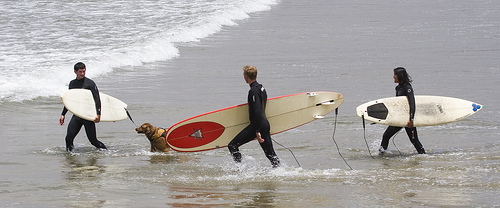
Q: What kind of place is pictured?
A: It is an ocean.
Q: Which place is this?
A: It is an ocean.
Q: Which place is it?
A: It is an ocean.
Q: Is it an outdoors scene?
A: Yes, it is outdoors.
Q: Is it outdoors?
A: Yes, it is outdoors.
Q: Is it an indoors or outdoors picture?
A: It is outdoors.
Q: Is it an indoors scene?
A: No, it is outdoors.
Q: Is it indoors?
A: No, it is outdoors.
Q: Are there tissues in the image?
A: No, there are no tissues.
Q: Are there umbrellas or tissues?
A: No, there are no tissues or umbrellas.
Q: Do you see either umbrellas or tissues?
A: No, there are no tissues or umbrellas.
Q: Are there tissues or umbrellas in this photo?
A: No, there are no tissues or umbrellas.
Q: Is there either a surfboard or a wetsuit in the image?
A: Yes, there is a wetsuit.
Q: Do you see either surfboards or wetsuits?
A: Yes, there is a wetsuit.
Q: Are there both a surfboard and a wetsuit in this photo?
A: Yes, there are both a wetsuit and a surfboard.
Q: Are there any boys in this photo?
A: No, there are no boys.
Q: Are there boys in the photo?
A: No, there are no boys.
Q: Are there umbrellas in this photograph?
A: No, there are no umbrellas.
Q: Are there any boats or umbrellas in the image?
A: No, there are no umbrellas or boats.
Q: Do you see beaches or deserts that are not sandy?
A: No, there is a beach but it is sandy.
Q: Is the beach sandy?
A: Yes, the beach is sandy.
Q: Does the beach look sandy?
A: Yes, the beach is sandy.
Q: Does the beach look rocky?
A: No, the beach is sandy.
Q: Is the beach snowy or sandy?
A: The beach is sandy.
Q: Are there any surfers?
A: Yes, there is a surfer.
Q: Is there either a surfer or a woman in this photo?
A: Yes, there is a surfer.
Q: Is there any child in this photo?
A: No, there are no children.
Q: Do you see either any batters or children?
A: No, there are no children or batters.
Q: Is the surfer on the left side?
A: Yes, the surfer is on the left of the image.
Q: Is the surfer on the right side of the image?
A: No, the surfer is on the left of the image.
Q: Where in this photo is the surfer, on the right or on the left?
A: The surfer is on the left of the image.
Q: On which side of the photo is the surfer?
A: The surfer is on the left of the image.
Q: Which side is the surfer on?
A: The surfer is on the left of the image.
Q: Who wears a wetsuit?
A: The surfer wears a wetsuit.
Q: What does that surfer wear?
A: The surfer wears a wetsuit.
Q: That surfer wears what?
A: The surfer wears a wetsuit.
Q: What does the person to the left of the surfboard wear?
A: The surfer wears a wetsuit.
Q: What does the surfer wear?
A: The surfer wears a wetsuit.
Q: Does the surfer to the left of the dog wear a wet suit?
A: Yes, the surfer wears a wet suit.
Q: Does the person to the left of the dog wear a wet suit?
A: Yes, the surfer wears a wet suit.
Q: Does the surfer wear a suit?
A: No, the surfer wears a wet suit.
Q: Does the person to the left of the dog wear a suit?
A: No, the surfer wears a wet suit.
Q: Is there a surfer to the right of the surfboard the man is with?
A: No, the surfer is to the left of the surfboard.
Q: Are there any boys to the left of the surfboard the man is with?
A: No, there is a surfer to the left of the surfboard.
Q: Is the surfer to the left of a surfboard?
A: Yes, the surfer is to the left of a surfboard.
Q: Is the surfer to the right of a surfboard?
A: No, the surfer is to the left of a surfboard.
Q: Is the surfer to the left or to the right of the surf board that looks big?
A: The surfer is to the left of the surfboard.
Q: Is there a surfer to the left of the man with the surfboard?
A: Yes, there is a surfer to the left of the man.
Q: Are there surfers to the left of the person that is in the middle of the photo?
A: Yes, there is a surfer to the left of the man.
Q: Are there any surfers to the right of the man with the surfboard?
A: No, the surfer is to the left of the man.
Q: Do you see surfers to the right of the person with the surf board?
A: No, the surfer is to the left of the man.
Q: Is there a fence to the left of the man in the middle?
A: No, there is a surfer to the left of the man.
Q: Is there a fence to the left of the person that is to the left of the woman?
A: No, there is a surfer to the left of the man.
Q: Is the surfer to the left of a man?
A: Yes, the surfer is to the left of a man.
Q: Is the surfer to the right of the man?
A: No, the surfer is to the left of the man.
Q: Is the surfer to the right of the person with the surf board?
A: No, the surfer is to the left of the man.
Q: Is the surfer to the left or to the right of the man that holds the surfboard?
A: The surfer is to the left of the man.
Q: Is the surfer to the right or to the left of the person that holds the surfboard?
A: The surfer is to the left of the man.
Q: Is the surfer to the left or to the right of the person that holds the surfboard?
A: The surfer is to the left of the man.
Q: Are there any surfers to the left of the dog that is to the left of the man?
A: Yes, there is a surfer to the left of the dog.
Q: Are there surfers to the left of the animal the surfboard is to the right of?
A: Yes, there is a surfer to the left of the dog.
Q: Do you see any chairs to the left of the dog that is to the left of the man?
A: No, there is a surfer to the left of the dog.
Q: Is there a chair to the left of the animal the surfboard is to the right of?
A: No, there is a surfer to the left of the dog.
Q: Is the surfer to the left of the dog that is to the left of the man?
A: Yes, the surfer is to the left of the dog.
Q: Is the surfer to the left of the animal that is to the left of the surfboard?
A: Yes, the surfer is to the left of the dog.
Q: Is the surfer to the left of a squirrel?
A: No, the surfer is to the left of the dog.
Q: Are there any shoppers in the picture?
A: No, there are no shoppers.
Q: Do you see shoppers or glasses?
A: No, there are no shoppers or glasses.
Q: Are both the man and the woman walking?
A: Yes, both the man and the woman are walking.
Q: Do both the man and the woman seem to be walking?
A: Yes, both the man and the woman are walking.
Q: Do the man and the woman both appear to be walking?
A: Yes, both the man and the woman are walking.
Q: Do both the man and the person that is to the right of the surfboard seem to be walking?
A: Yes, both the man and the woman are walking.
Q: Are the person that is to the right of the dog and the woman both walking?
A: Yes, both the man and the woman are walking.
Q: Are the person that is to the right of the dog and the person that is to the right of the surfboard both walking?
A: Yes, both the man and the woman are walking.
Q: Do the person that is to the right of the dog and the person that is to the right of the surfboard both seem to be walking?
A: Yes, both the man and the woman are walking.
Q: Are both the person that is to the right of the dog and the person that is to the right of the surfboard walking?
A: Yes, both the man and the woman are walking.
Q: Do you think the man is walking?
A: Yes, the man is walking.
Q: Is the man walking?
A: Yes, the man is walking.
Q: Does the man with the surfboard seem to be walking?
A: Yes, the man is walking.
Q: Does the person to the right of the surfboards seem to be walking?
A: Yes, the man is walking.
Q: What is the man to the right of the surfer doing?
A: The man is walking.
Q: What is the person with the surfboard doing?
A: The man is walking.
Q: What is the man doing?
A: The man is walking.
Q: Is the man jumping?
A: No, the man is walking.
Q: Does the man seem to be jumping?
A: No, the man is walking.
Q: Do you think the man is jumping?
A: No, the man is walking.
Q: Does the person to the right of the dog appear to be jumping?
A: No, the man is walking.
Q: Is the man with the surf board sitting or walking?
A: The man is walking.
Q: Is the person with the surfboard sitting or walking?
A: The man is walking.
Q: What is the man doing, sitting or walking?
A: The man is walking.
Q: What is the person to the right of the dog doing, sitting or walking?
A: The man is walking.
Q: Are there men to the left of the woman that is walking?
A: Yes, there is a man to the left of the woman.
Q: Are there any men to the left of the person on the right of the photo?
A: Yes, there is a man to the left of the woman.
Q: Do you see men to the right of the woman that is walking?
A: No, the man is to the left of the woman.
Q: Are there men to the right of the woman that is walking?
A: No, the man is to the left of the woman.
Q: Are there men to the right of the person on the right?
A: No, the man is to the left of the woman.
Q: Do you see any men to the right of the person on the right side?
A: No, the man is to the left of the woman.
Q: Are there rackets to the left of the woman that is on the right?
A: No, there is a man to the left of the woman.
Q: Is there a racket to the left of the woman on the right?
A: No, there is a man to the left of the woman.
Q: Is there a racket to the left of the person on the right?
A: No, there is a man to the left of the woman.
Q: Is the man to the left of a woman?
A: Yes, the man is to the left of a woman.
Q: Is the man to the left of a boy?
A: No, the man is to the left of a woman.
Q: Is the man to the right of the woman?
A: No, the man is to the left of the woman.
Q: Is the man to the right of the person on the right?
A: No, the man is to the left of the woman.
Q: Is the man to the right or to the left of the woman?
A: The man is to the left of the woman.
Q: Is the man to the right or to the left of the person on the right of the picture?
A: The man is to the left of the woman.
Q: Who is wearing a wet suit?
A: The man is wearing a wet suit.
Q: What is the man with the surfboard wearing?
A: The man is wearing a wet suit.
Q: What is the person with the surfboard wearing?
A: The man is wearing a wet suit.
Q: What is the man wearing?
A: The man is wearing a wet suit.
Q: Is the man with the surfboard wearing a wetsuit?
A: Yes, the man is wearing a wetsuit.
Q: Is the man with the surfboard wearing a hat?
A: No, the man is wearing a wetsuit.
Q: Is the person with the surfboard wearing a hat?
A: No, the man is wearing a wetsuit.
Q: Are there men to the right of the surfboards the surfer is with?
A: Yes, there is a man to the right of the surfboards.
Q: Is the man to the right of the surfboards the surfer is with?
A: Yes, the man is to the right of the surfboards.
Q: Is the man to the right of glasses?
A: No, the man is to the right of the surfboards.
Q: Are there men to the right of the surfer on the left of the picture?
A: Yes, there is a man to the right of the surfer.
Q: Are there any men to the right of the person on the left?
A: Yes, there is a man to the right of the surfer.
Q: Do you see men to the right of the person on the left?
A: Yes, there is a man to the right of the surfer.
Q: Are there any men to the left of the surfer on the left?
A: No, the man is to the right of the surfer.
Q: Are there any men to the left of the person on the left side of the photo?
A: No, the man is to the right of the surfer.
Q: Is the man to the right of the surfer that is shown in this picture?
A: Yes, the man is to the right of the surfer.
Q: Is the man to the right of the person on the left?
A: Yes, the man is to the right of the surfer.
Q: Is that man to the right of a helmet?
A: No, the man is to the right of the surfer.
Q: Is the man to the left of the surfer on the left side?
A: No, the man is to the right of the surfer.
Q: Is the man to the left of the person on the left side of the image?
A: No, the man is to the right of the surfer.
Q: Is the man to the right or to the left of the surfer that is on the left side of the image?
A: The man is to the right of the surfer.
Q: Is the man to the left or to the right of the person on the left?
A: The man is to the right of the surfer.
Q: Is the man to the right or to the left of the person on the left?
A: The man is to the right of the surfer.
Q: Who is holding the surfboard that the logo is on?
A: The man is holding the surfboard.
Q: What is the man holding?
A: The man is holding the surf board.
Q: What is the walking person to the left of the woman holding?
A: The man is holding the surf board.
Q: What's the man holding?
A: The man is holding the surf board.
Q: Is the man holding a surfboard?
A: Yes, the man is holding a surfboard.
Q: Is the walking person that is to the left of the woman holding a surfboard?
A: Yes, the man is holding a surfboard.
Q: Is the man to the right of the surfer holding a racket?
A: No, the man is holding a surfboard.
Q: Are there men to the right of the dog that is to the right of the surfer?
A: Yes, there is a man to the right of the dog.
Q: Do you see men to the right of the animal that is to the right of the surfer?
A: Yes, there is a man to the right of the dog.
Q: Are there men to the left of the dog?
A: No, the man is to the right of the dog.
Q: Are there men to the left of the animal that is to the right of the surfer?
A: No, the man is to the right of the dog.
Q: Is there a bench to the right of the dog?
A: No, there is a man to the right of the dog.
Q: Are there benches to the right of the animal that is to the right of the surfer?
A: No, there is a man to the right of the dog.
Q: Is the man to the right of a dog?
A: Yes, the man is to the right of a dog.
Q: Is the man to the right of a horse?
A: No, the man is to the right of a dog.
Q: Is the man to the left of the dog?
A: No, the man is to the right of the dog.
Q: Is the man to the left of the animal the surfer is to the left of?
A: No, the man is to the right of the dog.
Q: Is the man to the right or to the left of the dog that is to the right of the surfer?
A: The man is to the right of the dog.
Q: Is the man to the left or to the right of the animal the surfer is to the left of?
A: The man is to the right of the dog.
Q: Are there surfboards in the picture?
A: Yes, there is a surfboard.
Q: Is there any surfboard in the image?
A: Yes, there is a surfboard.